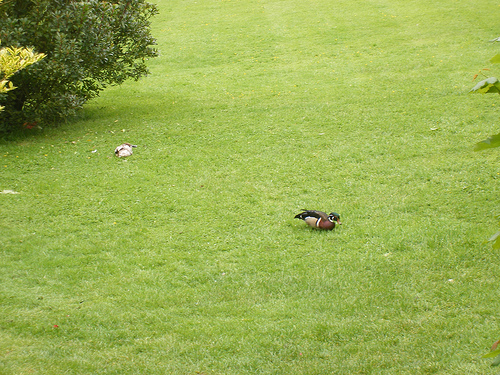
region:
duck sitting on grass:
[289, 202, 346, 242]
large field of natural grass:
[61, 188, 267, 354]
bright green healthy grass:
[91, 185, 264, 343]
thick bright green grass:
[152, 179, 224, 248]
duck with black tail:
[288, 199, 348, 240]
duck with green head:
[321, 204, 353, 230]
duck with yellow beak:
[324, 207, 350, 230]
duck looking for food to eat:
[109, 137, 143, 167]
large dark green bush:
[7, 3, 207, 128]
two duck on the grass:
[109, 137, 355, 243]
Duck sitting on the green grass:
[295, 202, 342, 237]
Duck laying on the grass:
[112, 136, 139, 161]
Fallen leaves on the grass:
[3, 139, 101, 169]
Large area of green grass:
[163, 2, 474, 188]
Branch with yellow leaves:
[0, 39, 47, 97]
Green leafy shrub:
[0, 1, 163, 131]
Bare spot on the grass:
[2, 181, 19, 202]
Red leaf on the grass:
[49, 321, 66, 337]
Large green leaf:
[472, 127, 497, 164]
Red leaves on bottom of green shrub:
[19, 115, 42, 135]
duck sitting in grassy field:
[272, 187, 366, 264]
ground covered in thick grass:
[85, 189, 292, 371]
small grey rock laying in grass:
[428, 258, 479, 306]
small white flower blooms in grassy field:
[30, 130, 86, 176]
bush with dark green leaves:
[47, 0, 169, 83]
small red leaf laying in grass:
[49, 319, 62, 337]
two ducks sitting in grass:
[82, 139, 374, 274]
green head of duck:
[327, 208, 349, 231]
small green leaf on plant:
[462, 65, 498, 101]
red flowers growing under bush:
[13, 112, 50, 139]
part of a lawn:
[319, 314, 350, 357]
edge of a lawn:
[172, 225, 197, 297]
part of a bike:
[311, 205, 315, 217]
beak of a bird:
[337, 215, 346, 231]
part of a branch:
[106, 23, 132, 53]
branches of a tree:
[131, 28, 158, 49]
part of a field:
[211, 283, 230, 339]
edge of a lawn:
[121, 185, 158, 257]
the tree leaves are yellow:
[0, 39, 48, 103]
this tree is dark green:
[5, 6, 160, 161]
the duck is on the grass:
[287, 196, 343, 231]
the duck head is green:
[329, 212, 341, 219]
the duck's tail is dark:
[289, 203, 321, 221]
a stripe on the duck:
[314, 216, 321, 230]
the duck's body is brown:
[300, 216, 336, 231]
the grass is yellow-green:
[20, 5, 484, 367]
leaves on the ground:
[0, 119, 142, 175]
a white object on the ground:
[106, 137, 137, 165]